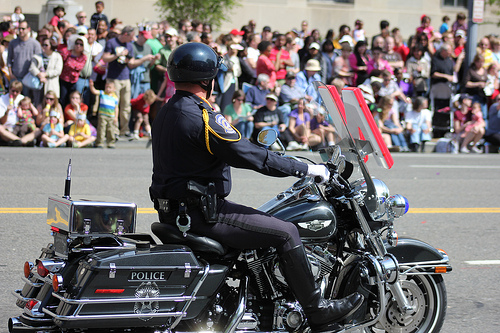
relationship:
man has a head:
[11, 21, 41, 101] [19, 21, 28, 40]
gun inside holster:
[188, 177, 218, 203] [190, 178, 224, 234]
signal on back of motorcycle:
[35, 256, 74, 298] [6, 84, 446, 332]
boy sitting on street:
[69, 112, 96, 148] [1, 140, 499, 332]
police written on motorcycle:
[126, 267, 171, 288] [6, 84, 446, 332]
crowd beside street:
[0, 3, 500, 146] [1, 140, 499, 332]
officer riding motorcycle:
[147, 39, 365, 328] [6, 84, 446, 332]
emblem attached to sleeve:
[213, 113, 239, 139] [194, 101, 311, 179]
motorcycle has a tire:
[6, 84, 446, 332] [356, 262, 445, 331]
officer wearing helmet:
[147, 39, 365, 328] [166, 39, 223, 92]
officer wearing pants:
[147, 39, 365, 328] [164, 197, 306, 251]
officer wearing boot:
[147, 39, 365, 328] [282, 242, 362, 328]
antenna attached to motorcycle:
[67, 20, 94, 201] [6, 84, 446, 332]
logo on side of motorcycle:
[301, 218, 333, 231] [6, 84, 446, 332]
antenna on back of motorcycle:
[67, 20, 94, 201] [6, 84, 446, 332]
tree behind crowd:
[157, 1, 239, 41] [0, 3, 500, 146]